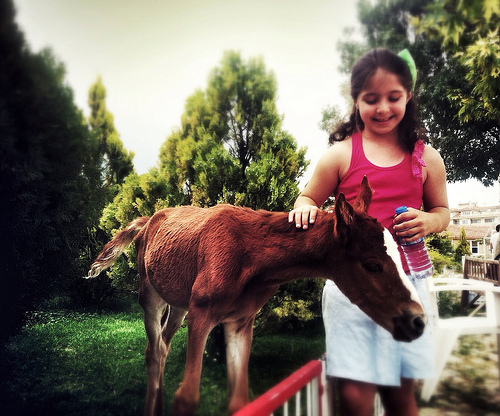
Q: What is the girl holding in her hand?
A: A water bottle.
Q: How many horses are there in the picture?
A: One.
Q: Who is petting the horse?
A: The girl.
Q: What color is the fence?
A: Red and white.